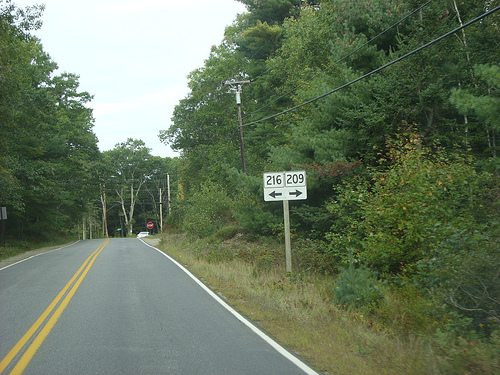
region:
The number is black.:
[295, 172, 306, 186]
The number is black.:
[291, 172, 300, 186]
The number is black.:
[283, 171, 293, 189]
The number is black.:
[273, 171, 284, 188]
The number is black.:
[271, 170, 278, 190]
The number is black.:
[263, 171, 274, 188]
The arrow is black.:
[286, 184, 306, 199]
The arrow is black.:
[266, 188, 286, 200]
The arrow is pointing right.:
[283, 185, 305, 200]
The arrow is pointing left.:
[263, 187, 284, 201]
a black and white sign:
[257, 165, 325, 230]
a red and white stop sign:
[144, 216, 165, 237]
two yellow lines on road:
[14, 227, 107, 373]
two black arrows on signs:
[256, 190, 326, 205]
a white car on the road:
[128, 220, 168, 250]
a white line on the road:
[130, 210, 368, 371]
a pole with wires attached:
[218, 65, 276, 226]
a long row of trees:
[151, 30, 497, 330]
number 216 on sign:
[262, 167, 284, 189]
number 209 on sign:
[283, 170, 309, 190]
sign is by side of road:
[262, 169, 309, 270]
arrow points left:
[263, 187, 285, 199]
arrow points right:
[285, 188, 305, 198]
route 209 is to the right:
[284, 171, 304, 184]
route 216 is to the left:
[262, 172, 283, 186]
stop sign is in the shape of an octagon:
[145, 219, 152, 229]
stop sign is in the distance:
[146, 220, 153, 234]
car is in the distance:
[135, 230, 150, 238]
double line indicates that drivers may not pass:
[2, 236, 112, 374]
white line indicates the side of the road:
[137, 236, 319, 373]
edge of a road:
[233, 315, 237, 323]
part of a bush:
[361, 258, 388, 284]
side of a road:
[178, 318, 184, 323]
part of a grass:
[341, 273, 349, 288]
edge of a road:
[211, 283, 213, 286]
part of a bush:
[235, 288, 243, 305]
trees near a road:
[193, 68, 234, 109]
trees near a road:
[287, 49, 322, 83]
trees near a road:
[38, 113, 102, 140]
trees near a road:
[31, 141, 95, 190]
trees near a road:
[383, 195, 423, 236]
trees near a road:
[11, 82, 73, 130]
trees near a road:
[1, 52, 50, 79]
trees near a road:
[0, 18, 42, 53]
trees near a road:
[424, 13, 445, 32]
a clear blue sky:
[127, 30, 164, 70]